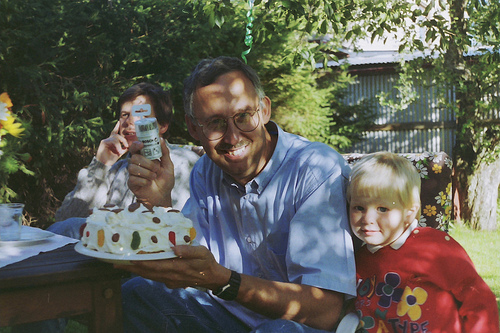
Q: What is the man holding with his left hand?
A: A cake.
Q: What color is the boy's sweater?
A: Red.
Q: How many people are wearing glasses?
A: One.